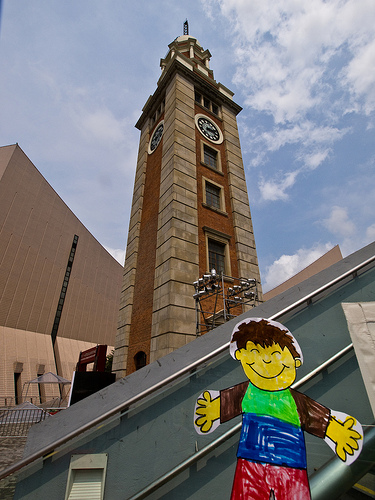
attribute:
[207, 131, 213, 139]
numeral — roman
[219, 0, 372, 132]
clouds — white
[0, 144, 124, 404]
building — black part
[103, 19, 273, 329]
tower — brown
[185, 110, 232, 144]
clock — tower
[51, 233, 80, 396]
bar — metal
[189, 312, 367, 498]
figure — human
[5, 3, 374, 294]
clouds — white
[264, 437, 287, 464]
marker — colored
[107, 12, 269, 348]
tower — clock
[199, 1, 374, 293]
clouds — white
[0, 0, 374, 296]
sky — blue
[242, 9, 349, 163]
clouds — white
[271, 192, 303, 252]
sky — blue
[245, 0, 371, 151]
clouds — white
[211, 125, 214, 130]
numeral — roman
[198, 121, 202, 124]
numeral — roman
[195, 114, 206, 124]
numeral — roman